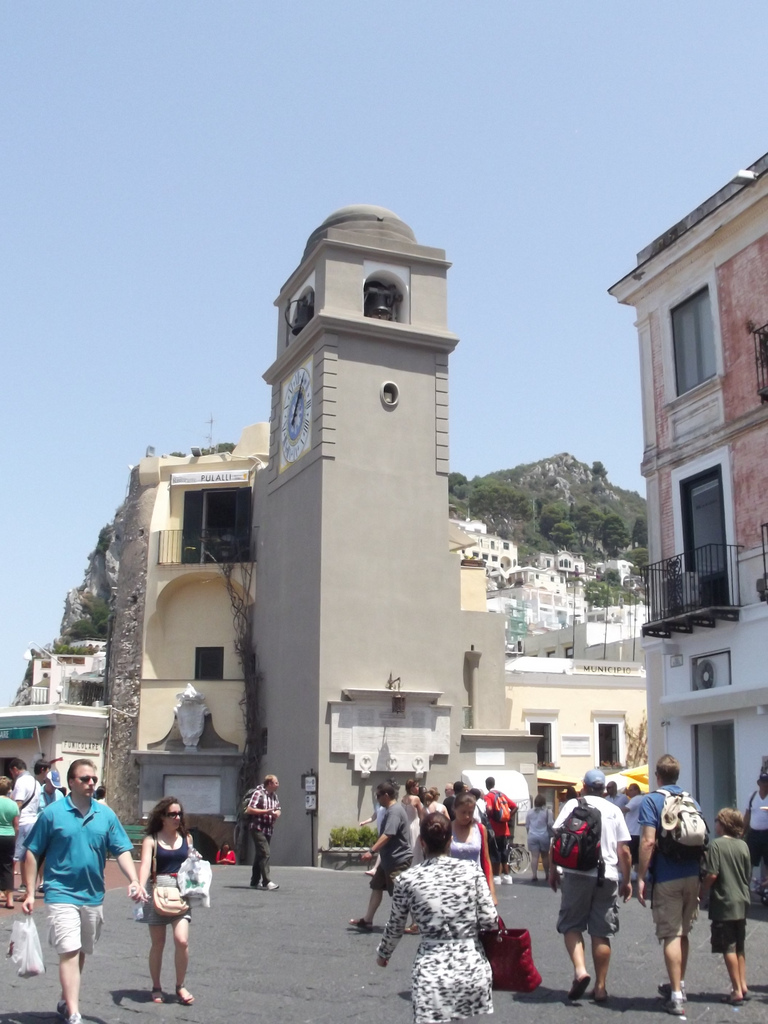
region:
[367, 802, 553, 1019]
woman carrying a red bag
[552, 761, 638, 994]
man wearing a red and black backpack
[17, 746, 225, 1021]
man and woman holding hands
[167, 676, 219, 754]
statue on the building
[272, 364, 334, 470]
clock on the tower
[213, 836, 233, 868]
person wearing a red shirt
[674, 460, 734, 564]
door on the building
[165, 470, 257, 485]
sign above the window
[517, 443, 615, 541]
grassy cliff above the houses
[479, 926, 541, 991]
a woman carrying a red purse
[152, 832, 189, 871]
a woman wearing a black tank top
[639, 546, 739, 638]
a black metal balcony over a white wall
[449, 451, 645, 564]
top of a mountain surrounded by trees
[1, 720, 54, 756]
a blue and white small canopy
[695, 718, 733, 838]
an opened door on a white building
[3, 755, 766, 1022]
people walking on a street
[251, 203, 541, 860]
a gray and tall clock tower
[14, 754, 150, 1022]
man with a light blue shirt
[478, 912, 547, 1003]
red bag of a woman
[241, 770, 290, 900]
man in a plaid shirt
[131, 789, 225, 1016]
woman in a black tank top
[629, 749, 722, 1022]
man with a white backpack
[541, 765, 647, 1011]
man with a red and black backpack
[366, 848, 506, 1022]
white and black patterned dress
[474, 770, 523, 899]
person with a red shirt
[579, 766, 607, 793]
blue baseball cap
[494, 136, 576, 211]
the sky is clear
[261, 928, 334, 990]
the ground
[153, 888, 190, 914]
a tanned purse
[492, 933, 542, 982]
women carrying a purse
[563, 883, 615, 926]
man wearing shorts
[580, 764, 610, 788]
a hat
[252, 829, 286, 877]
grey pants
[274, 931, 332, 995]
the ground is grey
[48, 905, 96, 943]
man wearing white shorts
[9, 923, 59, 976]
man carrying a plastic bag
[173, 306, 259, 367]
a view of clouds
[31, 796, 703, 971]
a group of people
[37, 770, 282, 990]
a couple holding their hands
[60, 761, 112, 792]
face of the person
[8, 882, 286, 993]
legs of the person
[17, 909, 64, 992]
a bag holding by man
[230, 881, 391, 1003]
a clear view of road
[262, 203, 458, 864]
clock tower topped with dome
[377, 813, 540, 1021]
woman with red bag on arm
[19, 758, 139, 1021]
man in blue shirt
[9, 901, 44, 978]
hand holding white plastic bag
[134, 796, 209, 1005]
walking woman in short skirt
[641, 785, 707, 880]
bag strapped to man's back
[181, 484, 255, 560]
window with open shutters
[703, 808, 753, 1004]
back of boy in shorts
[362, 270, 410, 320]
black bell in arched opening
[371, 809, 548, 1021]
woman in black and white dress carrying red handbag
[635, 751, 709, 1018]
man carrying white backpack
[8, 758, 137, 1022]
man wearing blue polo shirt with white shorts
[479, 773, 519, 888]
person in red shirt carrying a red and black backpack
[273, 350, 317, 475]
clock with white face and blue numerals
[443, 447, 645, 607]
tall mountaintop with green trees and dirt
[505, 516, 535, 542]
green leaves on the tree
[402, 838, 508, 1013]
a person walking outside